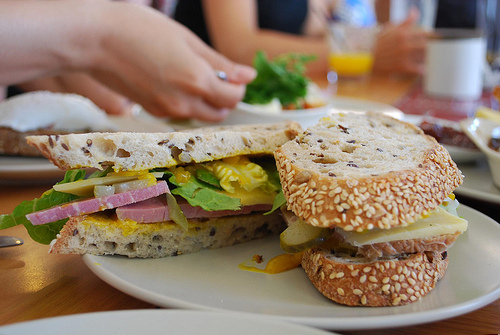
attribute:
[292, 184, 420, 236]
seeds — is round, are beige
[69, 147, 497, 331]
plate — white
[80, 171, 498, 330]
plate — is round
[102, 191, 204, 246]
meat — pink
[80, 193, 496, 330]
plate — is white, white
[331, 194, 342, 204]
seed — sesame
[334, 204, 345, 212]
seed — sesame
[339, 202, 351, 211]
seed — sesame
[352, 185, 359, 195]
seed — sesame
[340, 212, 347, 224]
seed — sesame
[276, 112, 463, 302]
sandwich — small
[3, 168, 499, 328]
table — brown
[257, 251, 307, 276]
mustard — yellow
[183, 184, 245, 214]
lettuce — green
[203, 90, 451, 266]
cheese — white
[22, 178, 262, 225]
meat — is pink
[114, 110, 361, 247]
sandwich — cut, halved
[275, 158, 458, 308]
sesame seeds — are beige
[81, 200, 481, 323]
plate — white